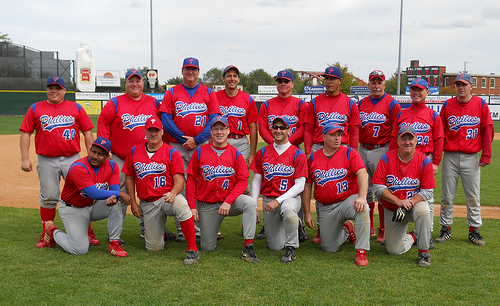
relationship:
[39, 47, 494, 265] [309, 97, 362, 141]
players wearing uniform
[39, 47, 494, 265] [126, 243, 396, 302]
players on field